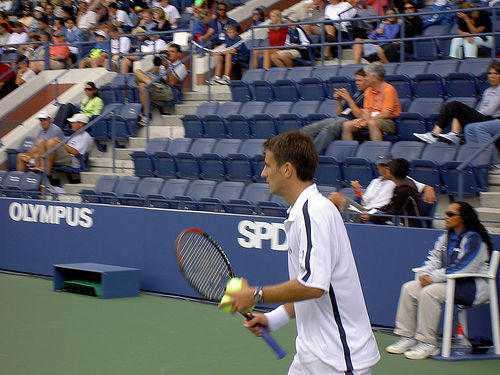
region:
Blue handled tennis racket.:
[172, 226, 286, 364]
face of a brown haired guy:
[259, 130, 316, 205]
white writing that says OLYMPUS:
[7, 199, 94, 229]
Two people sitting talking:
[330, 156, 440, 225]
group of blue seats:
[137, 132, 238, 182]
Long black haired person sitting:
[388, 200, 498, 360]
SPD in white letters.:
[237, 216, 289, 252]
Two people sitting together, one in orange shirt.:
[301, 63, 407, 154]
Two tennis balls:
[217, 276, 251, 311]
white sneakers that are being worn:
[386, 332, 441, 361]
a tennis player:
[178, 129, 381, 374]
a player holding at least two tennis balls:
[174, 130, 384, 371]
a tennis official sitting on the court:
[387, 196, 498, 361]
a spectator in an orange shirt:
[337, 55, 410, 150]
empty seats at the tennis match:
[87, 135, 252, 209]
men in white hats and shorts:
[11, 102, 99, 182]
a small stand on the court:
[36, 253, 153, 304]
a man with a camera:
[130, 39, 190, 126]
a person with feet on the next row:
[411, 59, 498, 150]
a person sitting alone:
[47, 75, 120, 135]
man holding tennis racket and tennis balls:
[152, 123, 388, 373]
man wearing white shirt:
[237, 123, 402, 373]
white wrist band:
[255, 286, 305, 337]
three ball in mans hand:
[210, 274, 262, 339]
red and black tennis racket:
[168, 187, 310, 373]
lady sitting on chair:
[384, 190, 499, 365]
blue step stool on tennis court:
[31, 242, 193, 321]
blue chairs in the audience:
[0, 8, 499, 351]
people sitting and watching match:
[23, 0, 498, 222]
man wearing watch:
[250, 284, 288, 324]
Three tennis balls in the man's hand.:
[215, 277, 265, 322]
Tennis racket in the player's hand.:
[155, 217, 287, 364]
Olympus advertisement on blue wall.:
[1, 187, 104, 239]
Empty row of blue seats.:
[130, 126, 492, 193]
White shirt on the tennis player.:
[267, 176, 388, 369]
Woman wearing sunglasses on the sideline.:
[378, 196, 496, 365]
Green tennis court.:
[0, 269, 498, 374]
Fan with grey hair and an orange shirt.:
[347, 52, 399, 143]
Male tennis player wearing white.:
[189, 129, 386, 371]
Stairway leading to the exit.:
[39, 71, 242, 221]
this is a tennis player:
[166, 129, 351, 371]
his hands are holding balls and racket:
[172, 226, 287, 348]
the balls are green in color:
[218, 280, 238, 310]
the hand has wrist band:
[267, 308, 289, 330]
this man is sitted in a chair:
[401, 203, 494, 352]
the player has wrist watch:
[250, 285, 268, 304]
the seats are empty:
[190, 84, 245, 194]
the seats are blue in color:
[110, 166, 235, 203]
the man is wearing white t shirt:
[302, 211, 331, 360]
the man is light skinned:
[292, 183, 294, 188]